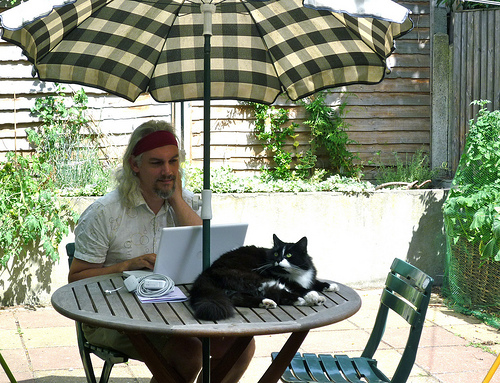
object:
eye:
[286, 253, 293, 258]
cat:
[187, 233, 338, 321]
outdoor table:
[50, 271, 359, 380]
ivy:
[23, 87, 90, 175]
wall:
[2, 0, 429, 179]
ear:
[128, 155, 139, 173]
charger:
[123, 273, 176, 298]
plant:
[438, 97, 498, 319]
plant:
[237, 95, 359, 175]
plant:
[1, 155, 83, 267]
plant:
[195, 162, 250, 188]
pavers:
[26, 347, 128, 369]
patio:
[2, 204, 497, 381]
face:
[143, 142, 179, 201]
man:
[67, 120, 255, 383]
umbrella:
[3, 0, 410, 104]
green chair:
[270, 257, 432, 381]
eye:
[274, 252, 279, 257]